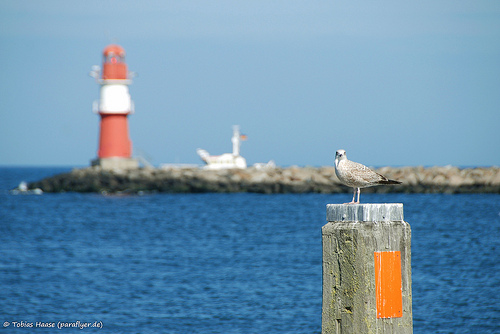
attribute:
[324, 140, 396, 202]
seagull — small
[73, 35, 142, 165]
lighthouse — red, white, white anbd orange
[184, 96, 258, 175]
ship — here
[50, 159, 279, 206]
rocks — here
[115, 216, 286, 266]
water — blue, here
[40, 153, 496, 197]
peninsula — manmade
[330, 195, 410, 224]
cap — small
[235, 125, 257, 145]
flag — flying, here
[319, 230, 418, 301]
pole — cement, concrete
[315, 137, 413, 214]
bird — tiny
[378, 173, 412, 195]
tail — black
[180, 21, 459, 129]
sky — blue, clear, here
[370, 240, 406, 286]
painting — orange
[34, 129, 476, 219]
island — here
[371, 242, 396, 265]
paint — orange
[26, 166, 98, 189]
stone — here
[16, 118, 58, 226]
lagoon — here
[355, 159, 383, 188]
wing — here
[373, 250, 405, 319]
sign — orange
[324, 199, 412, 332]
post — concrete